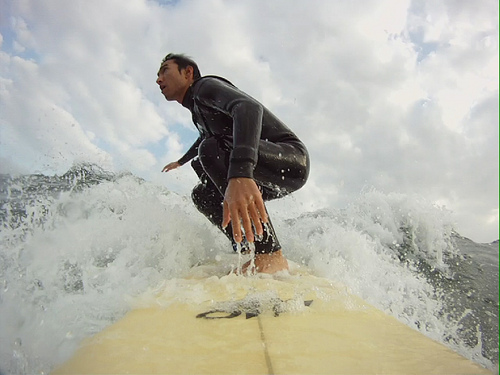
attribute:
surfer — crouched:
[148, 45, 320, 287]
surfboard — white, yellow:
[43, 253, 490, 373]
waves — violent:
[78, 208, 136, 284]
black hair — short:
[159, 53, 201, 78]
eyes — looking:
[160, 64, 167, 75]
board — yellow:
[181, 273, 296, 360]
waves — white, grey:
[1, 159, 498, 374]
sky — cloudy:
[4, 3, 480, 263]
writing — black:
[190, 288, 301, 328]